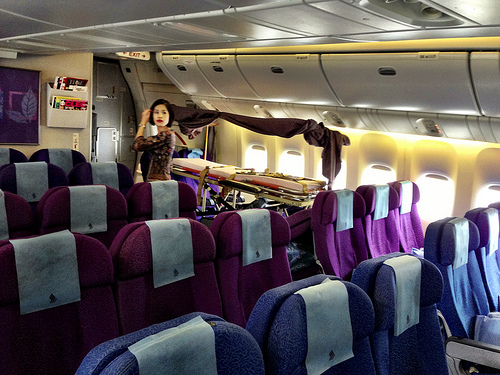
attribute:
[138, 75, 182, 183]
woman — dark-haired, standing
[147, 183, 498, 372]
seats — blue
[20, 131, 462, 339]
seats — pink, purple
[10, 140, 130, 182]
seats — purple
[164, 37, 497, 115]
storage — overhead, closed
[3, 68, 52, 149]
painting — purple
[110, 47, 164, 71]
sign — small, overhead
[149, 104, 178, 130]
hair — black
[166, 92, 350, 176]
curtain — brown